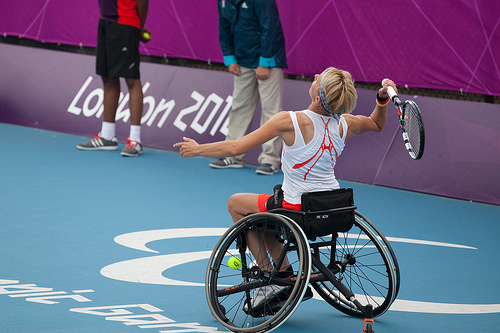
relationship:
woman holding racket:
[189, 65, 398, 284] [383, 77, 431, 163]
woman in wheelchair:
[189, 65, 398, 284] [205, 193, 401, 331]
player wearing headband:
[189, 65, 398, 284] [315, 69, 339, 114]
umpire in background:
[207, 1, 296, 175] [2, 1, 500, 203]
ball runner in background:
[69, 1, 153, 162] [2, 1, 500, 203]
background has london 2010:
[2, 1, 500, 203] [67, 72, 260, 155]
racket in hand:
[383, 77, 431, 163] [373, 79, 399, 102]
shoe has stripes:
[74, 134, 118, 152] [90, 135, 104, 151]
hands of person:
[227, 62, 274, 81] [207, 1, 296, 175]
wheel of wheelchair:
[206, 212, 311, 332] [205, 193, 401, 331]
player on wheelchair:
[189, 65, 398, 284] [205, 193, 401, 331]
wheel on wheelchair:
[363, 316, 379, 332] [205, 193, 401, 331]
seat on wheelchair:
[276, 189, 358, 236] [205, 193, 401, 331]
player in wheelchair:
[189, 65, 398, 284] [205, 193, 401, 331]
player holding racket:
[189, 65, 398, 284] [383, 77, 431, 163]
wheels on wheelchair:
[208, 209, 401, 328] [205, 193, 401, 331]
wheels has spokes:
[208, 209, 401, 328] [213, 222, 298, 327]